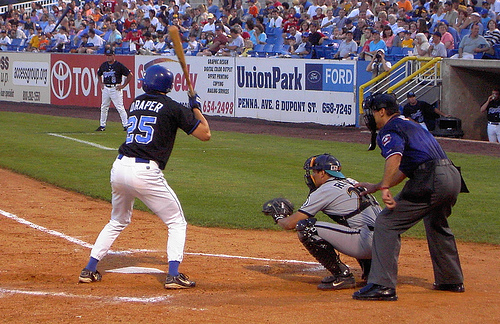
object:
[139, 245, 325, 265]
white line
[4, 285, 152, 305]
white line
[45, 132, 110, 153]
white line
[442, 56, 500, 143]
dugout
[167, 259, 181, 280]
blue socks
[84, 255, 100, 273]
blue socks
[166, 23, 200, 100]
wooden bat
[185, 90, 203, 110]
hand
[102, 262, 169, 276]
plate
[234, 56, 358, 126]
board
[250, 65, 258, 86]
blue letter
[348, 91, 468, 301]
umpire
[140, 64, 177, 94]
blue helmet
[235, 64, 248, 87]
blue ketter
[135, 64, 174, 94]
helmet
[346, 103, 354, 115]
blue letter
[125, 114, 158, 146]
25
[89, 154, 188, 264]
pants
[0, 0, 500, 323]
pictures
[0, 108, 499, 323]
ground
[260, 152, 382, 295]
man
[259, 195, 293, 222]
mitt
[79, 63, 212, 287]
man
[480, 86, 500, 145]
man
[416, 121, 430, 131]
pants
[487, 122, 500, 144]
pants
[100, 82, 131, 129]
pants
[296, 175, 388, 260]
uniform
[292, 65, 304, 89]
letter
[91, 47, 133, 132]
man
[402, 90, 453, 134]
man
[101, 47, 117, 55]
cap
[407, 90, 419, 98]
cap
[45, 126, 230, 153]
table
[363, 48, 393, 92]
man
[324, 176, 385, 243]
back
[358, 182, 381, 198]
hand